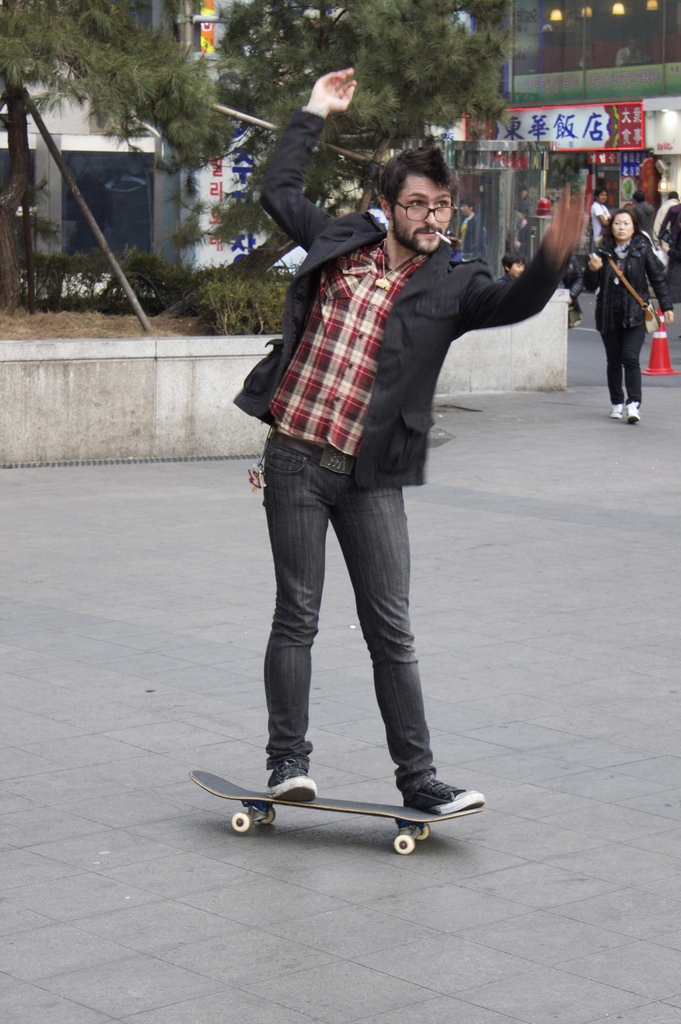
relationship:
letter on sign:
[465, 101, 644, 151] [484, 78, 652, 167]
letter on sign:
[619, 123, 631, 142] [505, 107, 642, 151]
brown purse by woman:
[599, 240, 662, 337] [587, 206, 674, 422]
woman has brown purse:
[587, 206, 674, 422] [599, 240, 662, 337]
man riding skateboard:
[229, 64, 594, 815] [186, 767, 484, 854]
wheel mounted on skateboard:
[231, 811, 252, 833] [186, 767, 484, 854]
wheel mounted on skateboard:
[260, 806, 274, 825] [186, 767, 484, 854]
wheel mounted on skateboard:
[392, 832, 415, 855] [186, 767, 484, 854]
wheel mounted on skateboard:
[414, 820, 431, 841] [186, 767, 484, 854]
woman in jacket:
[594, 193, 659, 394] [588, 229, 658, 321]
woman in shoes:
[594, 193, 659, 394] [593, 403, 647, 437]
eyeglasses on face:
[389, 191, 454, 221] [389, 180, 462, 264]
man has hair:
[229, 65, 594, 816] [402, 139, 456, 178]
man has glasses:
[229, 65, 594, 816] [385, 186, 458, 225]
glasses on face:
[385, 186, 458, 225] [389, 162, 464, 261]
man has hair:
[229, 65, 594, 816] [389, 210, 436, 263]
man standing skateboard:
[229, 65, 594, 816] [194, 737, 481, 870]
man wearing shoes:
[229, 65, 594, 816] [264, 756, 505, 829]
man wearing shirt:
[229, 65, 594, 816] [280, 225, 414, 476]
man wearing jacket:
[229, 65, 594, 816] [256, 116, 572, 506]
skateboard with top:
[180, 765, 489, 860] [181, 770, 479, 818]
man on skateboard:
[229, 64, 594, 815] [186, 767, 484, 854]